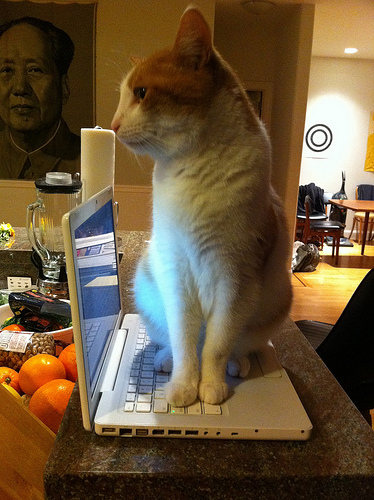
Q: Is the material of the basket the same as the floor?
A: Yes, both the basket and the floor are made of wood.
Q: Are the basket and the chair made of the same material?
A: Yes, both the basket and the chair are made of wood.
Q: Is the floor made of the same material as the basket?
A: Yes, both the floor and the basket are made of wood.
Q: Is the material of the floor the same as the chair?
A: Yes, both the floor and the chair are made of wood.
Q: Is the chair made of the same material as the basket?
A: Yes, both the chair and the basket are made of wood.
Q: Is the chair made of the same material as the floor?
A: Yes, both the chair and the floor are made of wood.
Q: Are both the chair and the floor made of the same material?
A: Yes, both the chair and the floor are made of wood.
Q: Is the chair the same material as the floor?
A: Yes, both the chair and the floor are made of wood.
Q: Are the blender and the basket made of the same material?
A: No, the blender is made of glass and the basket is made of wood.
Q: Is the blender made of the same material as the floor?
A: No, the blender is made of glass and the floor is made of wood.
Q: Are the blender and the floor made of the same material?
A: No, the blender is made of glass and the floor is made of wood.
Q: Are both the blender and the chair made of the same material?
A: No, the blender is made of glass and the chair is made of wood.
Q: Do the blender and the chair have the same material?
A: No, the blender is made of glass and the chair is made of wood.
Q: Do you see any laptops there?
A: Yes, there is a laptop.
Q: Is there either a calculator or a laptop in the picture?
A: Yes, there is a laptop.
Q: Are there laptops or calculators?
A: Yes, there is a laptop.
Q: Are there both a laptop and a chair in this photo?
A: Yes, there are both a laptop and a chair.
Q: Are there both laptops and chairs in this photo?
A: Yes, there are both a laptop and a chair.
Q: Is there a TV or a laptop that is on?
A: Yes, the laptop is on.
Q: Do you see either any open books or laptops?
A: Yes, there is an open laptop.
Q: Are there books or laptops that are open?
A: Yes, the laptop is open.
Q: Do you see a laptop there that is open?
A: Yes, there is an open laptop.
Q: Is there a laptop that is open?
A: Yes, there is a laptop that is open.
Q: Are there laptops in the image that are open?
A: Yes, there is a laptop that is open.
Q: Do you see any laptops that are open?
A: Yes, there is a laptop that is open.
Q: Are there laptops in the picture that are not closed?
A: Yes, there is a open laptop.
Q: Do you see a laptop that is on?
A: Yes, there is a laptop that is on.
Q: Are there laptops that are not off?
A: Yes, there is a laptop that is on.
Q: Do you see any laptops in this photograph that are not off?
A: Yes, there is a laptop that is on .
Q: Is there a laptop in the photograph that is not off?
A: Yes, there is a laptop that is on.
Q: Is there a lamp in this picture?
A: No, there are no lamps.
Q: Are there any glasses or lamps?
A: No, there are no lamps or glasses.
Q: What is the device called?
A: The device is a laptop.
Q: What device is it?
A: The device is a laptop.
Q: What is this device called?
A: This is a laptop.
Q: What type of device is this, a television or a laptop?
A: This is a laptop.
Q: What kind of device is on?
A: The device is a laptop.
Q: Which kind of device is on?
A: The device is a laptop.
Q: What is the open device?
A: The device is a laptop.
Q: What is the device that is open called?
A: The device is a laptop.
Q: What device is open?
A: The device is a laptop.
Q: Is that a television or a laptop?
A: That is a laptop.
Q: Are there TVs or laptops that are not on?
A: No, there is a laptop but it is on.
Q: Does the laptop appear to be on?
A: Yes, the laptop is on.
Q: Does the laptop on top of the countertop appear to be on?
A: Yes, the laptop computer is on.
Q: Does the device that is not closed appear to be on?
A: Yes, the laptop computer is on.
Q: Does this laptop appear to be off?
A: No, the laptop is on.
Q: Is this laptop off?
A: No, the laptop is on.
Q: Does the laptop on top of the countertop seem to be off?
A: No, the laptop is on.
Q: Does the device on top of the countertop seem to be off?
A: No, the laptop is on.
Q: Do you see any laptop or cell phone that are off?
A: No, there is a laptop but it is on.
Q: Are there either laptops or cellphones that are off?
A: No, there is a laptop but it is on.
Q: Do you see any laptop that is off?
A: No, there is a laptop but it is on.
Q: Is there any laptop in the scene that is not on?
A: No, there is a laptop but it is on.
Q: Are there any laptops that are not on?
A: No, there is a laptop but it is on.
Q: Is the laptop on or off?
A: The laptop is on.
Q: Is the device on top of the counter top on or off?
A: The laptop is on.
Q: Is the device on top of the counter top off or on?
A: The laptop is on.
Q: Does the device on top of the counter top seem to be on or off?
A: The laptop is on.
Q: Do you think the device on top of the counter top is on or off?
A: The laptop is on.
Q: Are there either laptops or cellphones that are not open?
A: No, there is a laptop but it is open.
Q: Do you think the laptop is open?
A: Yes, the laptop is open.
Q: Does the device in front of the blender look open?
A: Yes, the laptop is open.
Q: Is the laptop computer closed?
A: No, the laptop computer is open.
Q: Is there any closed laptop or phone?
A: No, there is a laptop but it is open.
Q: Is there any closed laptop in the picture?
A: No, there is a laptop but it is open.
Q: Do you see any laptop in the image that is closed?
A: No, there is a laptop but it is open.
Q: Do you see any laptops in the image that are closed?
A: No, there is a laptop but it is open.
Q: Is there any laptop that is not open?
A: No, there is a laptop but it is open.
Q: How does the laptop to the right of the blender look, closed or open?
A: The laptop is open.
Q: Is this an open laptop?
A: Yes, this is an open laptop.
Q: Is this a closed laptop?
A: No, this is an open laptop.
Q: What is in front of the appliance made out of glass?
A: The laptop is in front of the blender.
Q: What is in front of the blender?
A: The laptop is in front of the blender.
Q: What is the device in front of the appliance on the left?
A: The device is a laptop.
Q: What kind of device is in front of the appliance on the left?
A: The device is a laptop.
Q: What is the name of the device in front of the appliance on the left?
A: The device is a laptop.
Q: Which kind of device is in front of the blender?
A: The device is a laptop.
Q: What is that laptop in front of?
A: The laptop is in front of the blender.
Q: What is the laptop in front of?
A: The laptop is in front of the blender.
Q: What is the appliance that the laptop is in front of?
A: The appliance is a blender.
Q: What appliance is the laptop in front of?
A: The laptop is in front of the blender.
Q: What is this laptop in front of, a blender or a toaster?
A: The laptop is in front of a blender.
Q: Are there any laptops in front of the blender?
A: Yes, there is a laptop in front of the blender.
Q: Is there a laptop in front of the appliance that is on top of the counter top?
A: Yes, there is a laptop in front of the blender.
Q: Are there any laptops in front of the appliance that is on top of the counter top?
A: Yes, there is a laptop in front of the blender.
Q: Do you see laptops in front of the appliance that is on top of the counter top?
A: Yes, there is a laptop in front of the blender.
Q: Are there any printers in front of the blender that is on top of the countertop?
A: No, there is a laptop in front of the blender.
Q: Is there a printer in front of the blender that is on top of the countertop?
A: No, there is a laptop in front of the blender.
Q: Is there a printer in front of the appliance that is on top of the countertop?
A: No, there is a laptop in front of the blender.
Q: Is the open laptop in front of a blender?
A: Yes, the laptop is in front of a blender.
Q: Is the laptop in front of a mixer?
A: No, the laptop is in front of a blender.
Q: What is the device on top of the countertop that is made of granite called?
A: The device is a laptop.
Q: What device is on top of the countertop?
A: The device is a laptop.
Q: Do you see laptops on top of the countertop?
A: Yes, there is a laptop on top of the countertop.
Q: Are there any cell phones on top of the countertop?
A: No, there is a laptop on top of the countertop.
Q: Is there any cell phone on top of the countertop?
A: No, there is a laptop on top of the countertop.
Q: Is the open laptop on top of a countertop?
A: Yes, the laptop is on top of a countertop.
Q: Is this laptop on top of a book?
A: No, the laptop is on top of a countertop.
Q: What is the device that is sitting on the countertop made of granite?
A: The device is a laptop.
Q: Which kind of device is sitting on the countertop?
A: The device is a laptop.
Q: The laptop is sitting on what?
A: The laptop is sitting on the counter top.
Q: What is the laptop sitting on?
A: The laptop is sitting on the counter top.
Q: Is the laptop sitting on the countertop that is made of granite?
A: Yes, the laptop is sitting on the countertop.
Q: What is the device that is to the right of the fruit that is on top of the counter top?
A: The device is a laptop.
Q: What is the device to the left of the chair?
A: The device is a laptop.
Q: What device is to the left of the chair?
A: The device is a laptop.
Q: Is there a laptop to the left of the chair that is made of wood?
A: Yes, there is a laptop to the left of the chair.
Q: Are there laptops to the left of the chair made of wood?
A: Yes, there is a laptop to the left of the chair.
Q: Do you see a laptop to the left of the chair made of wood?
A: Yes, there is a laptop to the left of the chair.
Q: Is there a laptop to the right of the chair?
A: No, the laptop is to the left of the chair.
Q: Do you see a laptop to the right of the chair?
A: No, the laptop is to the left of the chair.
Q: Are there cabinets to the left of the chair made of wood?
A: No, there is a laptop to the left of the chair.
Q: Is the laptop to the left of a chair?
A: Yes, the laptop is to the left of a chair.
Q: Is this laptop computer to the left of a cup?
A: No, the laptop computer is to the left of a chair.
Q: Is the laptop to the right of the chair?
A: No, the laptop is to the left of the chair.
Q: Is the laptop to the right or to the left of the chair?
A: The laptop is to the left of the chair.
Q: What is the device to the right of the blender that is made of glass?
A: The device is a laptop.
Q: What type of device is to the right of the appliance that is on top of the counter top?
A: The device is a laptop.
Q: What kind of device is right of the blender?
A: The device is a laptop.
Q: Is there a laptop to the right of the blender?
A: Yes, there is a laptop to the right of the blender.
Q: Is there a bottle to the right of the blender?
A: No, there is a laptop to the right of the blender.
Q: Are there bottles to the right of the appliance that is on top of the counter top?
A: No, there is a laptop to the right of the blender.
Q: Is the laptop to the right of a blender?
A: Yes, the laptop is to the right of a blender.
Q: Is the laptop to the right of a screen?
A: No, the laptop is to the right of a blender.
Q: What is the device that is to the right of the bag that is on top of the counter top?
A: The device is a laptop.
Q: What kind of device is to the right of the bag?
A: The device is a laptop.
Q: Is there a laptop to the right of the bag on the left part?
A: Yes, there is a laptop to the right of the bag.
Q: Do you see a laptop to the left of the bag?
A: No, the laptop is to the right of the bag.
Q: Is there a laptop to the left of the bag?
A: No, the laptop is to the right of the bag.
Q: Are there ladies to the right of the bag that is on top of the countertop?
A: No, there is a laptop to the right of the bag.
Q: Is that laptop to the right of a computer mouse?
A: No, the laptop is to the right of the bag.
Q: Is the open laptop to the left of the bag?
A: No, the laptop is to the right of the bag.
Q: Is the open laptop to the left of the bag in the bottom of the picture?
A: No, the laptop is to the right of the bag.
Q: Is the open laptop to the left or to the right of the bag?
A: The laptop is to the right of the bag.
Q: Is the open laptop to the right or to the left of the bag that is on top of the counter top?
A: The laptop is to the right of the bag.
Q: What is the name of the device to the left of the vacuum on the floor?
A: The device is a laptop.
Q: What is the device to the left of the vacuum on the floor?
A: The device is a laptop.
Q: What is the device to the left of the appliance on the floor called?
A: The device is a laptop.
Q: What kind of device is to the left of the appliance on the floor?
A: The device is a laptop.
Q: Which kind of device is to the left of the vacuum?
A: The device is a laptop.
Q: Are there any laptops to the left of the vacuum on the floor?
A: Yes, there is a laptop to the left of the vacuum.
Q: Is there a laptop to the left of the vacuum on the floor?
A: Yes, there is a laptop to the left of the vacuum.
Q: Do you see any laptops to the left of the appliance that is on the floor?
A: Yes, there is a laptop to the left of the vacuum.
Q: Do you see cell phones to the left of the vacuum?
A: No, there is a laptop to the left of the vacuum.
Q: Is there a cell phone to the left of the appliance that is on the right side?
A: No, there is a laptop to the left of the vacuum.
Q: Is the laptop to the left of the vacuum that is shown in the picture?
A: Yes, the laptop is to the left of the vacuum.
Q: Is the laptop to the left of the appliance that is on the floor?
A: Yes, the laptop is to the left of the vacuum.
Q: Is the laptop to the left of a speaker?
A: No, the laptop is to the left of the vacuum.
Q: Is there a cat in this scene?
A: Yes, there is a cat.